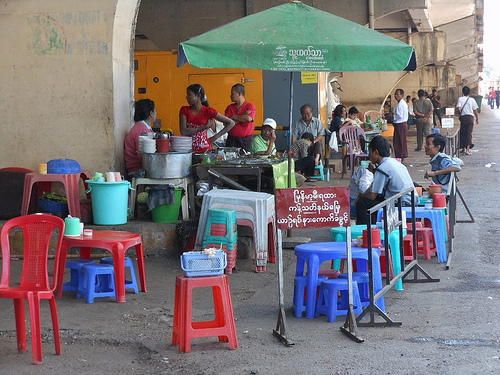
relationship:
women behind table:
[125, 82, 235, 170] [194, 149, 291, 204]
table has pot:
[194, 149, 291, 204] [206, 147, 240, 186]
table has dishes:
[194, 149, 291, 204] [165, 133, 197, 154]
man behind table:
[249, 115, 278, 153] [194, 149, 291, 204]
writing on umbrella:
[266, 45, 333, 73] [177, 4, 417, 180]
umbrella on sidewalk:
[177, 4, 417, 180] [271, 89, 499, 338]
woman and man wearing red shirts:
[178, 70, 257, 152] [179, 109, 261, 135]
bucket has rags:
[85, 174, 130, 225] [92, 167, 104, 180]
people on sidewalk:
[388, 86, 483, 155] [271, 89, 499, 338]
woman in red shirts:
[179, 86, 239, 153] [179, 103, 215, 151]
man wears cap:
[249, 115, 278, 153] [264, 119, 278, 130]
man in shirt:
[228, 82, 262, 140] [229, 99, 259, 139]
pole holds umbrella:
[288, 76, 299, 192] [177, 4, 417, 180]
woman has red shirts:
[179, 86, 239, 153] [179, 103, 215, 151]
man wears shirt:
[249, 115, 278, 153] [251, 134, 280, 156]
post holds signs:
[438, 105, 460, 132] [444, 105, 456, 133]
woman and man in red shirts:
[128, 70, 263, 167] [120, 105, 253, 156]